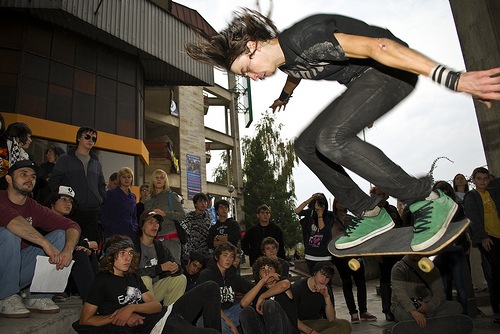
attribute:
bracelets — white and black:
[395, 39, 479, 111]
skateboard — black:
[390, 313, 474, 332]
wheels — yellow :
[417, 252, 438, 272]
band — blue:
[101, 236, 142, 254]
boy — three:
[290, 267, 342, 330]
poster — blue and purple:
[174, 139, 224, 247]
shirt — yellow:
[473, 188, 498, 235]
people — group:
[9, 166, 301, 318]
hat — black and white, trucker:
[50, 177, 72, 196]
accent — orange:
[0, 113, 152, 166]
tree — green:
[204, 109, 306, 256]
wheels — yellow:
[344, 254, 434, 276]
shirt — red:
[4, 190, 69, 245]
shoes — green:
[331, 185, 462, 255]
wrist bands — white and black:
[427, 58, 464, 97]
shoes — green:
[345, 196, 456, 251]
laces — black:
[411, 203, 441, 235]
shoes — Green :
[333, 187, 458, 251]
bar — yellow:
[0, 111, 151, 164]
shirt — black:
[268, 28, 422, 90]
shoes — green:
[325, 177, 465, 280]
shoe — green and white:
[408, 188, 458, 249]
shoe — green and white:
[335, 208, 393, 252]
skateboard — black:
[329, 218, 470, 272]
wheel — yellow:
[345, 256, 360, 274]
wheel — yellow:
[418, 257, 435, 274]